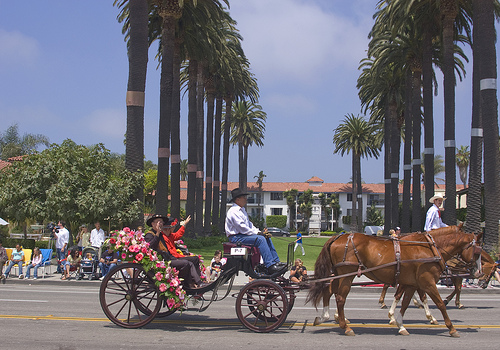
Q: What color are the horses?
A: Brown.